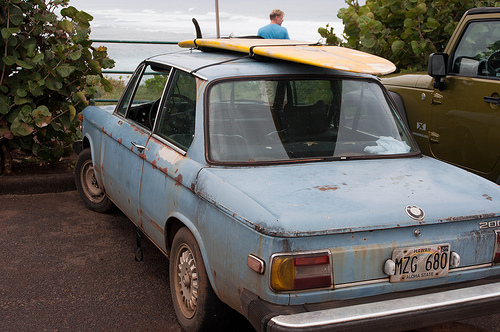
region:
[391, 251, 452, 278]
the license plate is white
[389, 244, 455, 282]
the plate number is MZG 680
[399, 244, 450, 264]
a rainbow is at the top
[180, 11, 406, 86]
a surf board is tied to the roof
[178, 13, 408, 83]
the surfboard is yellow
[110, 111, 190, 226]
there is rust on the door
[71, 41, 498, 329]
the car is a bmw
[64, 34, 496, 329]
the car is baby blue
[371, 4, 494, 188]
a jeep is parked over to the side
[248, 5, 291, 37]
the man is watching the ocean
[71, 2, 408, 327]
car parked in parking lot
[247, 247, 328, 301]
back lights of car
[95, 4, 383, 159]
surf board on top of car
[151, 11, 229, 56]
black surf fin on car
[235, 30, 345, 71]
black tie down straps on board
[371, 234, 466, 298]
license plat on back of car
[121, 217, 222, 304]
back tire of car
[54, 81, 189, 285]
rusty brown spots on car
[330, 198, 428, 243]
logo on back of car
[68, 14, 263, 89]
ocean in background by car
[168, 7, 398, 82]
a yellow surfboard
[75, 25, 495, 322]
an old blue car with surfboard on top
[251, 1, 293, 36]
a person wearing blue shirt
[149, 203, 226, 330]
a wheel of an old car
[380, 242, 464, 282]
a plate number of an old car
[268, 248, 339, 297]
a back light of an old car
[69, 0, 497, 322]
a yellow surfboard tied on top of a blue car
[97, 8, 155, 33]
a body of water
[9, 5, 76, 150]
a plant with lots of leaves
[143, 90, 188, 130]
a stirring wheel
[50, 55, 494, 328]
an old blue car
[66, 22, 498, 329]
this is a car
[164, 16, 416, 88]
a yellow surf board on top of the car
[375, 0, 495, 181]
this is a car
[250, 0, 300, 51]
this is a person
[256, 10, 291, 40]
the person is wearing a blue shirt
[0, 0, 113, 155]
a tree with green leaves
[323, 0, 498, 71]
a tree with green leaves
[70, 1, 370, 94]
a cloudy sky in the background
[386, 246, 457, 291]
the number plates on the car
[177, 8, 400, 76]
yellow surfboard on top of a car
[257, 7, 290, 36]
man in a blue shirt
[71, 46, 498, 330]
rusty old BMW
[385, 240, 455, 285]
license plate on car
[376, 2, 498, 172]
Jeep parked next to car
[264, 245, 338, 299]
tail light on the car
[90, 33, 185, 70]
body of water in the distance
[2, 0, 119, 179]
tall foliage at the side of the curb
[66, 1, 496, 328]
two vehicles parked at the curb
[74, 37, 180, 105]
steel fence